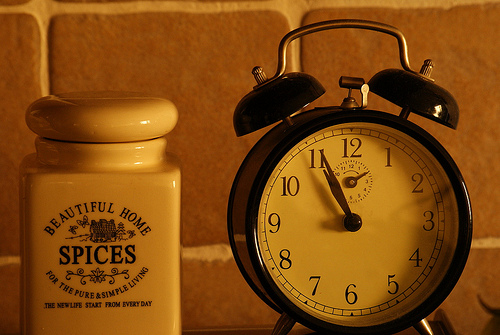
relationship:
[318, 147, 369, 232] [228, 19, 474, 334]
hands on alarm clock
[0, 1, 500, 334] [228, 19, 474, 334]
tiles behind alarm clock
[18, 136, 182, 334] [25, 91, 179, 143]
jar has a lid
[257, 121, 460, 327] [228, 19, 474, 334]
face of alarm clock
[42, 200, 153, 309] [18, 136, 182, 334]
letters on jar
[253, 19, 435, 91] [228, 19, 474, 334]
handle on alarm clock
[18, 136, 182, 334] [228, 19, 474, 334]
jar next to alarm clock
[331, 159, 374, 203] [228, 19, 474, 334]
small clock in alarm clock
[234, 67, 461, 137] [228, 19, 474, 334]
bells on alarm clock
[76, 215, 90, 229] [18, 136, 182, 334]
butterfly on jar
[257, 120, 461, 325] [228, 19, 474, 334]
10:56 on alarm clock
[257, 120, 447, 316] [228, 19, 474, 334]
10:56 on alarm clock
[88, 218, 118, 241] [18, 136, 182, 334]
building on jar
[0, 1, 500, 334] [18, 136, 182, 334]
tiles behind jar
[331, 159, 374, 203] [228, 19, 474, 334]
small clock on alarm clock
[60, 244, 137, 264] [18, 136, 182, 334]
spices on jar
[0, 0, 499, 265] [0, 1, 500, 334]
grout within tiles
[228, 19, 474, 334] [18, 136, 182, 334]
alarm clock next to jar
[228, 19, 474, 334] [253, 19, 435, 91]
alarm clock has a handle